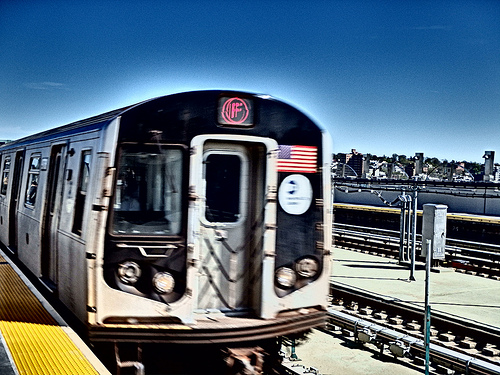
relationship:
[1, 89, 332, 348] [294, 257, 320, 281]
train has headlight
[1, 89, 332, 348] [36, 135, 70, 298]
train has door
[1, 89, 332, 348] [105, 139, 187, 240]
train has front window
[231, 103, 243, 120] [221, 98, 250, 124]
letter f in circle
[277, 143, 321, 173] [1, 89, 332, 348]
flag on train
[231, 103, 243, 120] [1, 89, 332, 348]
letter f on train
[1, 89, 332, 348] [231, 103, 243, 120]
train has letter f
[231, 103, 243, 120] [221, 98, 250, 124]
letter f has circle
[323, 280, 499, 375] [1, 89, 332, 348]
tracks are next to train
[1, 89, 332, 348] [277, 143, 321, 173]
train has flag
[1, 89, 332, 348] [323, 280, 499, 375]
train on tracks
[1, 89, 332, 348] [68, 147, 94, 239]
train has window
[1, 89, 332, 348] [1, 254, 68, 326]
train casting shadow